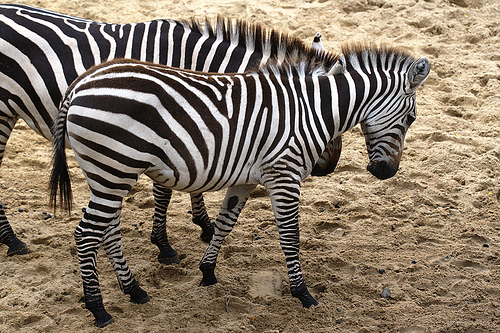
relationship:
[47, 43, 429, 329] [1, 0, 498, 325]
zebra on ground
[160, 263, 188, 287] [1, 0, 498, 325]
print in ground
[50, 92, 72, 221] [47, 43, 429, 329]
tail of zebra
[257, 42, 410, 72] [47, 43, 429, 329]
mane on zebra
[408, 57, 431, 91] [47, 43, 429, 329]
ear on zebra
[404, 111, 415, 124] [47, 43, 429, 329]
eye of zebra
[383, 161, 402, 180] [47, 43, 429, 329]
nose on zebra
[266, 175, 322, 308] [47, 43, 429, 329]
leg on zebra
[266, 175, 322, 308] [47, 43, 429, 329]
leg of zebra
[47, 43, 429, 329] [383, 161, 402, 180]
zebra has nose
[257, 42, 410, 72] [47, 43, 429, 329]
mane of zebra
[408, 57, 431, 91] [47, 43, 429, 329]
ear of zebra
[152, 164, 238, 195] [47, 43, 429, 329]
stomach of zebra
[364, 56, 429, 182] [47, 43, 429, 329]
head of zebra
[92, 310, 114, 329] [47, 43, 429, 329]
hoof of zebra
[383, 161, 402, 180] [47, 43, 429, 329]
nose of zebra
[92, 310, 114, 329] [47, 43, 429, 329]
hoof on zebra